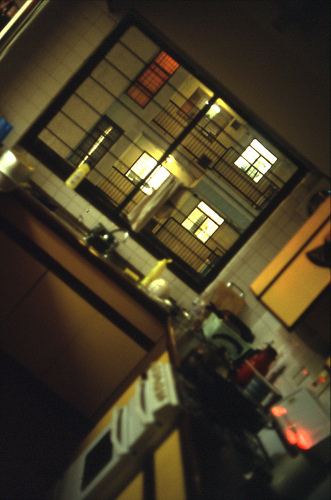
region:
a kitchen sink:
[52, 202, 157, 283]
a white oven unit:
[46, 346, 191, 490]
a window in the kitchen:
[34, 29, 297, 284]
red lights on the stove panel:
[270, 396, 315, 449]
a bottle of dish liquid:
[130, 238, 185, 297]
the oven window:
[64, 407, 133, 495]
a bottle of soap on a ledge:
[61, 137, 94, 202]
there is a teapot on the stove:
[170, 297, 270, 418]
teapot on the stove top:
[172, 313, 264, 418]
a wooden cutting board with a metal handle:
[180, 265, 257, 348]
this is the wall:
[43, 33, 78, 61]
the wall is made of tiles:
[249, 243, 268, 259]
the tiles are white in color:
[265, 229, 279, 246]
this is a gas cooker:
[56, 359, 177, 497]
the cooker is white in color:
[122, 417, 134, 431]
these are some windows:
[135, 140, 273, 239]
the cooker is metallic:
[124, 418, 136, 430]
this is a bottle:
[70, 159, 90, 186]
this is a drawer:
[32, 290, 82, 336]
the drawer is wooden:
[64, 298, 91, 347]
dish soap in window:
[61, 155, 96, 190]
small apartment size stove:
[49, 361, 178, 498]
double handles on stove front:
[107, 379, 154, 452]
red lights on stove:
[270, 400, 311, 458]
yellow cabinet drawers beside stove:
[150, 428, 181, 498]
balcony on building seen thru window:
[126, 65, 286, 215]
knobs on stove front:
[149, 362, 166, 403]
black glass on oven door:
[76, 430, 120, 494]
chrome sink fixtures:
[80, 216, 139, 263]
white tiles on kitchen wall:
[22, 42, 60, 95]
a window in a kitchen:
[19, 20, 303, 248]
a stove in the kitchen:
[93, 339, 329, 491]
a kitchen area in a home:
[60, 219, 318, 454]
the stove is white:
[55, 376, 212, 472]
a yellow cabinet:
[251, 194, 330, 338]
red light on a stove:
[262, 383, 323, 462]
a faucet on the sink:
[30, 193, 146, 271]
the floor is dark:
[11, 361, 84, 496]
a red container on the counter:
[242, 331, 284, 393]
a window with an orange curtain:
[124, 41, 174, 119]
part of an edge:
[153, 456, 160, 470]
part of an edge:
[174, 451, 197, 473]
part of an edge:
[174, 443, 182, 465]